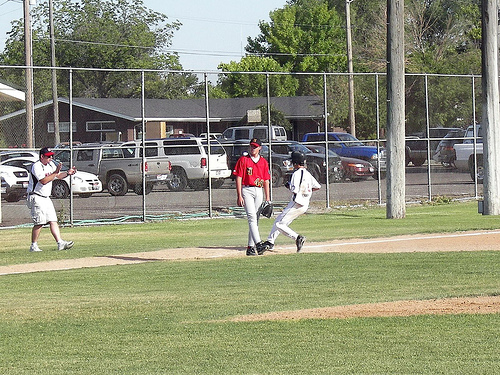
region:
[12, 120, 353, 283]
three people playing baseball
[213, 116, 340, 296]
two people playing baseball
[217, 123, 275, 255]
A baseball player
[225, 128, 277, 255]
A baseball player wearing a red shirt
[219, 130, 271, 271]
A baseball player wearing white pants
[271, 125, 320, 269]
A baseball player wearing a white shirt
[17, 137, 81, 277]
A man wearing white shorts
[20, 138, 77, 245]
A man wearing a blue and red cap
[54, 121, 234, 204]
Cars in a parking lot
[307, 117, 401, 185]
A blue truck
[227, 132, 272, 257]
a baseball player wearing red and white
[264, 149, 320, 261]
a baseball player wearing white and black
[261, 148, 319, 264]
a baseball player arriving at the base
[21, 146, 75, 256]
a coach standing off field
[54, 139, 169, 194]
a parked silver truck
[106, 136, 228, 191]
a parked white SUV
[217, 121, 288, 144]
a parked silver van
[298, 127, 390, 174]
a parked blue truck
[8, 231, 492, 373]
a gras baseball field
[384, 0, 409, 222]
a wooden telephone pole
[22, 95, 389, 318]
BASEBALL GAME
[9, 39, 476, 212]
CARS PARKED IN THE PARKING LOT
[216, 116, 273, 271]
A PLAYER IN RED AND WHITE BASEBALL UNIFORM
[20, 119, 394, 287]
Baseball coach on left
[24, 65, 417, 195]
Cars parked near a building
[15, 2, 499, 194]
Trees in the background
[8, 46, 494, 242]
Metal fence separating baseball field and parking lot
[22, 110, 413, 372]
Baseball field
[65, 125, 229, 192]
Grey truck and white SUV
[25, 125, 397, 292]
Baseball practice match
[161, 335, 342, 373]
Green grass on a baseball field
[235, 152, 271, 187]
Baseball player with a red jersey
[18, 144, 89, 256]
Third base coach on a baseball field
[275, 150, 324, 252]
Runner reaching third base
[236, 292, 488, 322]
Dirt from the pitcher's mound on a baseball field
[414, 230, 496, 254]
Infield dirt at a baseball field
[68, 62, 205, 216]
Chain link fence around a baseball field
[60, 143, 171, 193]
Grey truck in a parking lot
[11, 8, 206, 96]
Tree growing near a baseball field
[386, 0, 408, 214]
Wooden pole near a baseball field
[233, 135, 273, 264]
this is a man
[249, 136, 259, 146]
this is a cap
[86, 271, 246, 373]
this is a grass area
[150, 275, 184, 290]
the grass is green in color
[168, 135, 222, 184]
this is a vehicle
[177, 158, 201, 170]
the vehicle is white in color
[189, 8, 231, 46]
this is the sky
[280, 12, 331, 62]
this is a tree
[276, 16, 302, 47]
the tree has green leaves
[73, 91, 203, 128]
this is a house